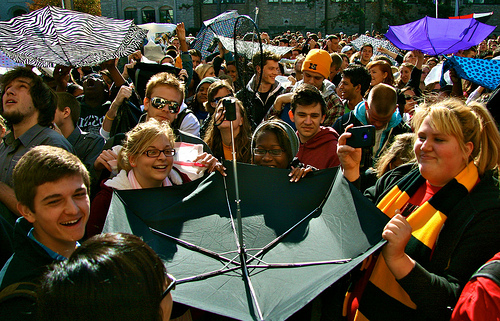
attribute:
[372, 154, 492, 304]
scarf — yellow, black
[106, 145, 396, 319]
umbrella — green